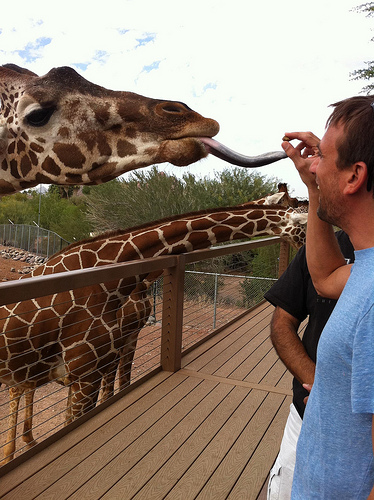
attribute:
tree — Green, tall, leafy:
[84, 186, 146, 235]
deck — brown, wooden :
[7, 346, 289, 498]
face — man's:
[308, 109, 360, 227]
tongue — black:
[191, 133, 290, 169]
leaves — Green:
[131, 172, 150, 183]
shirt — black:
[248, 228, 360, 412]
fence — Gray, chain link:
[1, 222, 278, 329]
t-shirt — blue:
[308, 264, 371, 456]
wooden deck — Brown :
[0, 298, 308, 498]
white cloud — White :
[278, 58, 314, 91]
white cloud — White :
[185, 13, 211, 26]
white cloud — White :
[172, 63, 189, 83]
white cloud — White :
[269, 101, 302, 120]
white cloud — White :
[52, 11, 94, 41]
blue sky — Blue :
[19, 49, 30, 60]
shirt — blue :
[286, 253, 373, 498]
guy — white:
[261, 229, 356, 498]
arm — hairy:
[268, 303, 315, 392]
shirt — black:
[244, 217, 367, 420]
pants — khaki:
[254, 403, 309, 497]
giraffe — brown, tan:
[10, 91, 219, 205]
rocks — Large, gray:
[6, 246, 44, 276]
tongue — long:
[192, 126, 319, 183]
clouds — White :
[5, 9, 347, 168]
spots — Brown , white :
[153, 209, 283, 251]